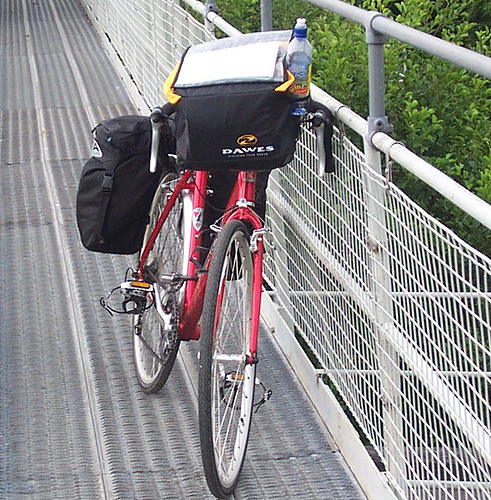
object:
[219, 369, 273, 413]
pedal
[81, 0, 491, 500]
wire screen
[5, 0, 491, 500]
bridge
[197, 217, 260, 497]
black tire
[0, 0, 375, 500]
metal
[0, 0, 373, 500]
roadway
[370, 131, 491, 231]
pipe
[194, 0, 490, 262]
bush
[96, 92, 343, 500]
bicycle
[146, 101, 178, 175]
bars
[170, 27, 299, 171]
bag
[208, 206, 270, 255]
brakes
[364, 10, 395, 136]
pole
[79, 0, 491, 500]
gate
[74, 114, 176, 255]
bag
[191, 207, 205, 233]
logo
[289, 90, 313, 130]
holder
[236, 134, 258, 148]
insignia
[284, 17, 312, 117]
bottle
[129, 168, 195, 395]
back tire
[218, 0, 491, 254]
leaves